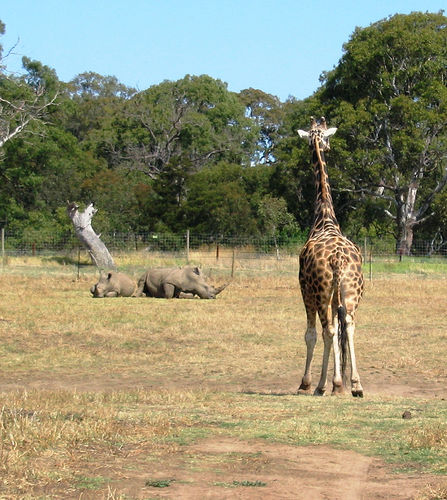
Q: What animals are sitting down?
A: Rhinos.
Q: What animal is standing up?
A: A giraffe.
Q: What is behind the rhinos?
A: A metal fence.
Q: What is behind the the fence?
A: There are green trees behind the fence.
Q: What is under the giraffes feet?
A: The grass in the field.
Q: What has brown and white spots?
A: The giraffe.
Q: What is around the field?
A: There is a fence.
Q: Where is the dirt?
A: The dirt is on the field.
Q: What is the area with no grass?
A: It's a bald spot.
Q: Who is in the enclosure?
A: There are animals in the enclosure.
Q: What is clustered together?
A: Two horned animals.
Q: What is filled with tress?
A: A forest.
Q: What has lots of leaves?
A: A tree.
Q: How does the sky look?
A: Clear.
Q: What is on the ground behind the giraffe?
A: Patch of dirt.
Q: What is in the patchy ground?
A: Dirt.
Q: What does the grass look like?
A: Dry.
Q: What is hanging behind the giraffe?
A: Tail.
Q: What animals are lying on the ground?
A: Rhinos.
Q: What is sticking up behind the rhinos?
A: Stump.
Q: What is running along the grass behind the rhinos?
A: Fence.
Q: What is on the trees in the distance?
A: Leaves.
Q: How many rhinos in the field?
A: Two.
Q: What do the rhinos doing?
A: Resting.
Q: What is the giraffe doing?
A: Watching the rhino.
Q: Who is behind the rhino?
A: No one.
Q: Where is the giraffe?
A: Few feet away from the rhinos.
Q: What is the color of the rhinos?
A: Brown.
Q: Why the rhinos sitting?
A: Resting.